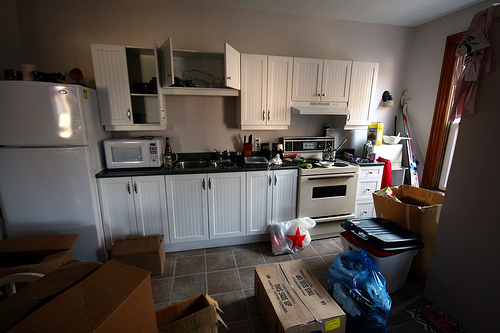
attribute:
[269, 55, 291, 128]
door — White 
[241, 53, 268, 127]
door — White , CUPBOARD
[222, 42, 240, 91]
door — White 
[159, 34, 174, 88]
door — White 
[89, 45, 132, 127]
door — White 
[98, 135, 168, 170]
microwave — White 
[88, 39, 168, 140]
cupboard — White 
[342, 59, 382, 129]
cupboard door — White 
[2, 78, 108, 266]
fridge — white 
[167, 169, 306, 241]
doors — CUPBOARD, WHITE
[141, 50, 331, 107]
doors — white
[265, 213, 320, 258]
plastic bag — WHITE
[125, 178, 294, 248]
cupboard — white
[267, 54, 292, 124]
door — WHITE, CUPBOARD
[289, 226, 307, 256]
star — RED